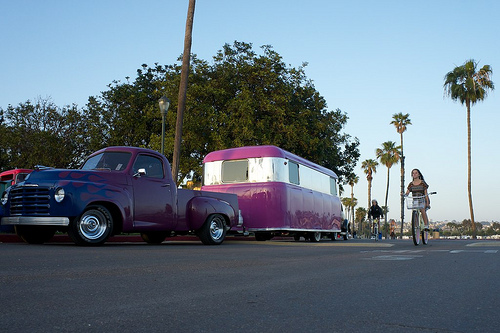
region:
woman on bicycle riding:
[390, 158, 442, 252]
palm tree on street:
[432, 58, 498, 237]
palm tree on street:
[388, 109, 415, 231]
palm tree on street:
[373, 129, 404, 223]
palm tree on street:
[358, 153, 378, 233]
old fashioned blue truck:
[10, 129, 245, 244]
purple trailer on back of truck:
[210, 121, 357, 250]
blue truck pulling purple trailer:
[11, 130, 351, 253]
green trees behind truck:
[38, 38, 365, 173]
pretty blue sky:
[1, 0, 493, 94]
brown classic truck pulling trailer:
[46, 160, 267, 242]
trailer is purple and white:
[218, 142, 314, 252]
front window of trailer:
[218, 157, 275, 215]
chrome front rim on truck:
[82, 213, 131, 258]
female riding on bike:
[402, 167, 443, 271]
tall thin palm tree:
[450, 74, 487, 253]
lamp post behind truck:
[133, 80, 185, 152]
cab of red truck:
[8, 159, 33, 197]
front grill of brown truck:
[6, 178, 55, 220]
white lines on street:
[401, 239, 466, 276]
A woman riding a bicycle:
[401, 163, 442, 247]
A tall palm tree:
[443, 55, 495, 237]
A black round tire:
[199, 208, 231, 250]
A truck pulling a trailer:
[1, 140, 346, 247]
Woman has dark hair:
[407, 165, 427, 184]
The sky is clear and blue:
[1, 2, 499, 223]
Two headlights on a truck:
[1, 187, 70, 208]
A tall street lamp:
[153, 91, 173, 157]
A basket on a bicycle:
[401, 192, 430, 213]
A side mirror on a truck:
[130, 162, 149, 184]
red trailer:
[207, 141, 329, 235]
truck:
[31, 143, 242, 250]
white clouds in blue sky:
[414, 123, 474, 164]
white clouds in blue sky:
[417, 136, 477, 183]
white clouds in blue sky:
[397, 32, 468, 69]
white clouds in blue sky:
[315, 45, 350, 87]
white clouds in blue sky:
[367, 15, 409, 76]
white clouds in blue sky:
[295, 0, 349, 45]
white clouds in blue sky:
[41, 29, 153, 83]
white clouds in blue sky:
[108, 41, 136, 69]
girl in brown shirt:
[401, 167, 431, 227]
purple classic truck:
[1, 143, 240, 244]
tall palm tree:
[443, 56, 493, 238]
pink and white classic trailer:
[202, 148, 343, 240]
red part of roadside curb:
[3, 233, 293, 241]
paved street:
[2, 239, 495, 329]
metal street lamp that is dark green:
[157, 94, 169, 153]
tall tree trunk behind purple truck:
[172, 0, 195, 183]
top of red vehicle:
[0, 168, 32, 184]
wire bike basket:
[405, 195, 425, 208]